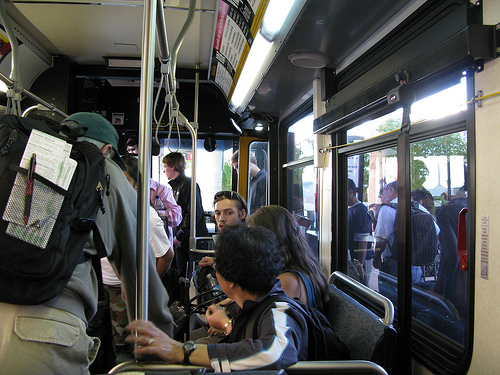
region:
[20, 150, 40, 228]
red and black pen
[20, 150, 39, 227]
pen clipped to backpack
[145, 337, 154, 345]
wedding ring on person's finger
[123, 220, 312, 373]
person wearing black watch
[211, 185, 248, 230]
person with sunglasses on head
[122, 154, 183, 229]
part of person in pink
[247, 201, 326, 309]
part of woman in blue top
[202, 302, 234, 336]
person's hand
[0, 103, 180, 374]
part of man in green hat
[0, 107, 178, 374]
man carrying backpack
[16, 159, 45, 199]
A pen in someones bag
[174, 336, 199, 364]
A man wearing a watch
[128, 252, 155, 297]
a pole in the train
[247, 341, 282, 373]
A boy in a white, and grey jacket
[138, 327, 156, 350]
a man wearing a ring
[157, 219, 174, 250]
someone in a white shirt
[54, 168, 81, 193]
papers in a mans bag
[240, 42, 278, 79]
lights in the train, or bus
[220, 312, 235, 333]
a women wearing a bracelet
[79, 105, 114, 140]
a man wearing a hat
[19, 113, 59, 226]
the papers in the backpack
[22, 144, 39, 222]
the pen on the backpack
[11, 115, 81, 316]
the man standings backpack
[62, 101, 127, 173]
hat on the man standings head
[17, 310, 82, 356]
back pocket of the man standing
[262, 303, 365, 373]
backpack on the woman sitting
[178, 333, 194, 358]
watch on the woman sitting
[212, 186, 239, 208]
sunglasses on the mans head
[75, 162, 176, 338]
hand sweatshirt of the man standing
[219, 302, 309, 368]
grey and white stripped shirt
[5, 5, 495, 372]
people travels in a bus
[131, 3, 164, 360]
a silver pole in a bus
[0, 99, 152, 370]
an old man holding a backpack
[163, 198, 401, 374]
people are sit in the bus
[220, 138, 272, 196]
a person in the doorstep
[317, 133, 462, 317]
people stand outside the bus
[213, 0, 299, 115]
lights on the bus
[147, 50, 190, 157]
straps hanging from a pole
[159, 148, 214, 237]
man wears black jacket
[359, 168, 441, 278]
person holding a backpack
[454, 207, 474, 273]
A red handle on the window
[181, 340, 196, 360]
a black wrist watch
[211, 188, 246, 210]
A pair of sunglasses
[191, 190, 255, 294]
A man with sunglasses on his head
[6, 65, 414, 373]
People riding on a bus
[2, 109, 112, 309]
A black backpack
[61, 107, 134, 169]
A green ball cap.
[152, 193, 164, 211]
A clear bottle with a blue cap.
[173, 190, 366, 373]
People sitting down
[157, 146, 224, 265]
A man getting onto the bus